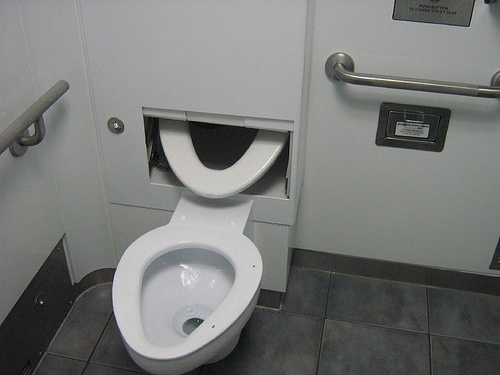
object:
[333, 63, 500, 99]
bar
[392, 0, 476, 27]
sign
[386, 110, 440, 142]
door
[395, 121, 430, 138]
label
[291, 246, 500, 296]
molding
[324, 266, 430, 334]
tile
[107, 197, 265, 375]
toilet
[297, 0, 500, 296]
wall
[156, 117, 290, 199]
toilet seat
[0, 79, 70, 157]
bar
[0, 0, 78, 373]
wall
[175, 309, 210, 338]
water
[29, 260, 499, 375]
floor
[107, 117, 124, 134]
flush button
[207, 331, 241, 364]
base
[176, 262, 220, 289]
light